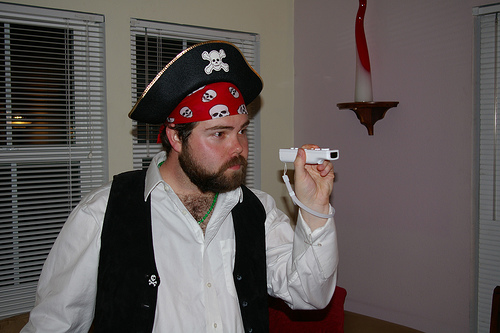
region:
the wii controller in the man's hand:
[278, 147, 338, 164]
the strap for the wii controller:
[281, 160, 334, 218]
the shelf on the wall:
[337, 99, 399, 135]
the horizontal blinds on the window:
[0, 0, 262, 320]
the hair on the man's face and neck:
[176, 135, 246, 193]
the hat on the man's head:
[127, 39, 263, 121]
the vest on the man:
[87, 168, 269, 331]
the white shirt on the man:
[19, 150, 339, 332]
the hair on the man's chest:
[175, 193, 220, 237]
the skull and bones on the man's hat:
[201, 49, 228, 74]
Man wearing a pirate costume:
[22, 38, 342, 331]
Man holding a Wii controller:
[15, 39, 344, 331]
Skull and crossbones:
[145, 268, 160, 293]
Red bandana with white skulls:
[153, 80, 248, 145]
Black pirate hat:
[125, 37, 265, 123]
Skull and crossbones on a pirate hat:
[197, 46, 232, 74]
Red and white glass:
[349, 0, 375, 103]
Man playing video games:
[13, 39, 340, 331]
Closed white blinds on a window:
[473, 10, 498, 332]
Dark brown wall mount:
[335, 98, 402, 138]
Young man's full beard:
[177, 130, 248, 194]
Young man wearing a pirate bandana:
[166, 83, 255, 125]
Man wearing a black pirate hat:
[127, 37, 265, 122]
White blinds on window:
[0, 13, 106, 303]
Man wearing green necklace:
[185, 190, 218, 224]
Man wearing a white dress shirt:
[17, 143, 345, 330]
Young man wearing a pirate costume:
[17, 35, 340, 331]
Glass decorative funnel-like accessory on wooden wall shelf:
[339, 0, 398, 140]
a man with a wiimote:
[273, 143, 341, 165]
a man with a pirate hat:
[122, 41, 274, 127]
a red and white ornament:
[346, 2, 381, 103]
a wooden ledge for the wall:
[333, 98, 401, 137]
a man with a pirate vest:
[89, 155, 274, 331]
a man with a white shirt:
[15, 147, 335, 331]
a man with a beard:
[173, 132, 251, 196]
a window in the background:
[3, 2, 100, 331]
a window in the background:
[126, 17, 271, 301]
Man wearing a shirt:
[12, 149, 345, 331]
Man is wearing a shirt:
[17, 149, 345, 331]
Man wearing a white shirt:
[15, 147, 342, 329]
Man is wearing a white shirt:
[12, 146, 344, 331]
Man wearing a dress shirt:
[15, 150, 345, 332]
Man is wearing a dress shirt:
[15, 146, 345, 331]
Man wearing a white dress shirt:
[16, 148, 346, 330]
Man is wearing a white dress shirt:
[13, 147, 345, 332]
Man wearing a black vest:
[82, 165, 272, 331]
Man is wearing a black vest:
[90, 165, 275, 331]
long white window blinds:
[1, 4, 105, 319]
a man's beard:
[175, 134, 247, 195]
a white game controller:
[273, 138, 342, 164]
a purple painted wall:
[294, 0, 478, 330]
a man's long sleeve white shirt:
[17, 162, 338, 332]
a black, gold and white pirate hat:
[125, 40, 267, 128]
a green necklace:
[157, 157, 222, 223]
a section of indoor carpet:
[344, 296, 423, 331]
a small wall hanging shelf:
[336, 96, 402, 134]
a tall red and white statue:
[348, 0, 380, 104]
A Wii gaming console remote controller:
[278, 146, 340, 166]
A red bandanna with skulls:
[168, 80, 258, 119]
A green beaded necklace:
[198, 190, 217, 223]